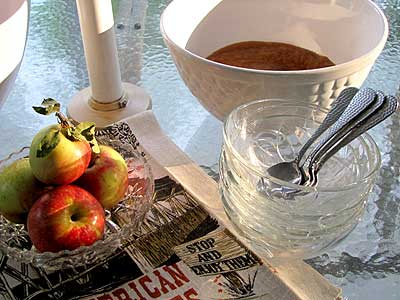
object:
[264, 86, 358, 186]
teaspoons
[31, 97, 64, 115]
leaves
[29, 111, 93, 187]
apple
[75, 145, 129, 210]
apples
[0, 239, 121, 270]
bowl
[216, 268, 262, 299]
sign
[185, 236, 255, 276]
lettering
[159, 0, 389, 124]
bowl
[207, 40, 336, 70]
liquid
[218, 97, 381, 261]
bowls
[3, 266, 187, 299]
newspaper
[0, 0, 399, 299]
table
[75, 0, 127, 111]
pole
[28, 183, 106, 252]
apple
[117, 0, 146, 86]
reflection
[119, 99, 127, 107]
bolt